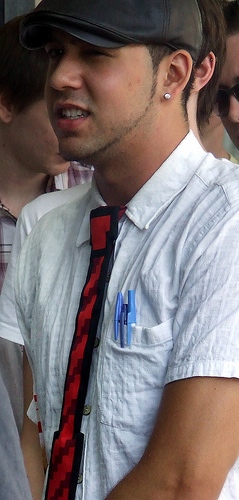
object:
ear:
[163, 48, 191, 101]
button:
[83, 403, 92, 416]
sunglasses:
[232, 84, 239, 100]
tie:
[58, 200, 126, 423]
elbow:
[164, 466, 199, 500]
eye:
[48, 48, 66, 58]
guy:
[15, 0, 239, 500]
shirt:
[0, 132, 239, 498]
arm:
[20, 333, 48, 498]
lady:
[0, 13, 96, 293]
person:
[212, 0, 239, 152]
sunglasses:
[217, 88, 230, 118]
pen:
[126, 289, 137, 346]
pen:
[120, 304, 128, 348]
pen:
[114, 292, 123, 340]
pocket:
[99, 316, 173, 434]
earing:
[164, 93, 170, 100]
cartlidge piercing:
[210, 57, 213, 61]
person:
[186, 0, 238, 168]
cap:
[18, 0, 203, 52]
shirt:
[0, 174, 96, 348]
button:
[105, 271, 110, 282]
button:
[92, 336, 99, 349]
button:
[76, 473, 83, 485]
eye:
[77, 48, 114, 59]